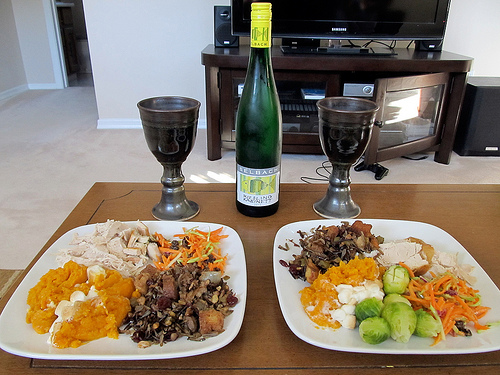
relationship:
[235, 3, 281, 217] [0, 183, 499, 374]
bottle on table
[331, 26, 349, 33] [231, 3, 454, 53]
logo on television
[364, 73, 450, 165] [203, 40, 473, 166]
door to cabinet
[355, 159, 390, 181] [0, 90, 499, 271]
controller on ground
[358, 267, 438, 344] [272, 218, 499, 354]
cabbage balls on plate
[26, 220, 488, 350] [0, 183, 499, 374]
food on table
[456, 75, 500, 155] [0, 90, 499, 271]
speaker on ground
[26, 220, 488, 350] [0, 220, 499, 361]
food on plates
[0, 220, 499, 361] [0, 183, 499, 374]
plates on table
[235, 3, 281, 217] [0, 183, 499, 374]
bottle of wine on table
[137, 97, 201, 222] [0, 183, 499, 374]
wine glass on table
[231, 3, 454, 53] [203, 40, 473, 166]
television on cabinet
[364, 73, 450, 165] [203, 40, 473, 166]
door on cabinet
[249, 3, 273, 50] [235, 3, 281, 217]
cap on bottle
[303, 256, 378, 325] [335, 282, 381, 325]
sweet potatoes with marshmallows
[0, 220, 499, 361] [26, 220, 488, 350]
plates of food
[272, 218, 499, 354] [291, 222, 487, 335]
plate of food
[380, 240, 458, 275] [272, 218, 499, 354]
chicken breast on plate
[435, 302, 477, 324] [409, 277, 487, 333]
carrots in salad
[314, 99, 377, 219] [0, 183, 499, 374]
goblet on table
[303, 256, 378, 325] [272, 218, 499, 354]
sweet potatoes on plate